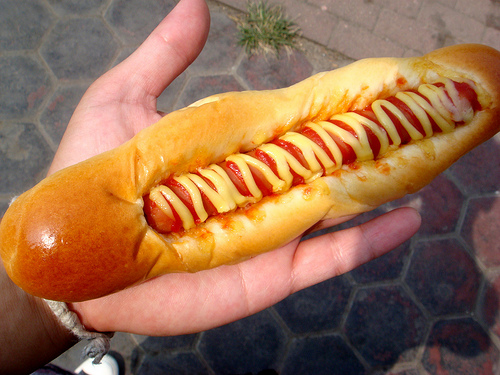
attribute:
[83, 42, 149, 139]
hand — open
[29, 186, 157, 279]
bun — big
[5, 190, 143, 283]
bun — brown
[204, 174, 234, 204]
mustard — yellow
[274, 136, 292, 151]
ketchup — red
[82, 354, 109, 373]
shoe — white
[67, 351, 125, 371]
shoe — white , top  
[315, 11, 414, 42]
bricks — grey 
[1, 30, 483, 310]
sandwich — yellow